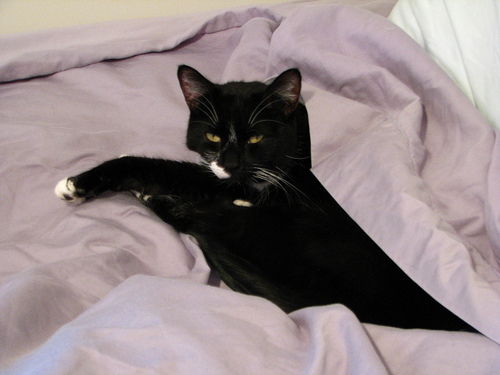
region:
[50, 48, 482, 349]
Black cat laying on blanket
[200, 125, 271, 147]
Green eyes of cat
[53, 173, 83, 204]
White tipped paw of cat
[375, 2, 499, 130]
Pillow in white pillowcase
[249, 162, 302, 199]
Whiskers of cat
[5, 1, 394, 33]
Carpeted floor in background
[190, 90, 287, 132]
Whiskers above cat's eyes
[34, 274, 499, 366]
blanket partially covering cat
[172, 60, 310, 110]
Alert ears on cat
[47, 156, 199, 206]
Crossed forelegs of cat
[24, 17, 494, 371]
black cat laying on sheet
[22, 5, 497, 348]
cat laying on purple sheet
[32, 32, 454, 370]
black cat laying on purple sheet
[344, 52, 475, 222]
wrinkles in purple sheet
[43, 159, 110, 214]
white tip on paw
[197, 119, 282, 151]
black cat's glowing eyes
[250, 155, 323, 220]
white whiskers on cat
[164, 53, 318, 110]
perky ears on cat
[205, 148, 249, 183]
white part on cats mouth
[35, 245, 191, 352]
wrinkle in purple sheet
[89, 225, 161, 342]
Comfortable lavender comforter.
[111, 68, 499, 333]
A cat laying ontop of lavender comforter..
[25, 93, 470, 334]
A black cat who owns a lavender comforter.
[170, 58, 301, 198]
A cat with white on his cheeks.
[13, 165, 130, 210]
A cat with black and white paw.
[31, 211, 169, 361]
A lavender wrinkled blanket.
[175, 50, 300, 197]
A black cat staring into your soul.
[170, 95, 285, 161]
A black cat with yellow eyes.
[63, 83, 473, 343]
A short haired black cat on a blanket.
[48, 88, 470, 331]
A tired black cat on a blanket.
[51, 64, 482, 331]
A tuxedo cat laying in blankets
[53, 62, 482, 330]
A black and white cat laying in a bed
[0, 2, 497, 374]
A light purple blanket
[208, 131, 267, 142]
Cat eyes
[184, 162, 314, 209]
Cat's mouth and whiskers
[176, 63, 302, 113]
The cat's ears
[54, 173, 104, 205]
The cat's paw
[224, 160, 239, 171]
The cat's nose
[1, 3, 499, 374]
A large purple blanket with a cat on it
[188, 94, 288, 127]
The cat's eyebrows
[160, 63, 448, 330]
A black cat is on the bed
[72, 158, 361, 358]
The cat is on pink sheets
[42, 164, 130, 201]
The cat has white paws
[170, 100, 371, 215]
The cat has yellow eyes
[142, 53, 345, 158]
The cat has two eyes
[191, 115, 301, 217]
The cat has white whiskers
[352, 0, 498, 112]
A white pillow is in the background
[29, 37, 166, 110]
The blanket has a fold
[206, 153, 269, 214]
The cat has a white patched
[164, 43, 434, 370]
The cat is in the blanket